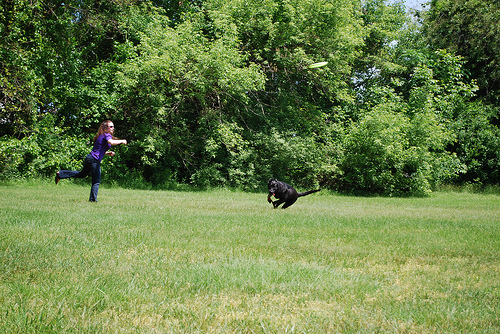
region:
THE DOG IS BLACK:
[260, 166, 328, 220]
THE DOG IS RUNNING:
[257, 172, 328, 220]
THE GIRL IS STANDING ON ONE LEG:
[46, 114, 135, 203]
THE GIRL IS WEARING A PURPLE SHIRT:
[83, 130, 116, 162]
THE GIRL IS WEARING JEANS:
[52, 153, 104, 199]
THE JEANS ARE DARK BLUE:
[56, 149, 102, 200]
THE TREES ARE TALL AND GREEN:
[1, 0, 499, 214]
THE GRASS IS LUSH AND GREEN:
[1, 178, 496, 332]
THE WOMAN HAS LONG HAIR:
[89, 118, 114, 138]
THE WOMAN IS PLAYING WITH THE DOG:
[48, 107, 325, 225]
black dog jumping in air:
[257, 173, 327, 217]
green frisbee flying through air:
[302, 55, 332, 76]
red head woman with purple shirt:
[51, 114, 138, 208]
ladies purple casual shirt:
[82, 128, 124, 164]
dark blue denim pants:
[42, 147, 112, 209]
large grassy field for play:
[14, 170, 492, 325]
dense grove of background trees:
[6, 4, 496, 205]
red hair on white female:
[91, 118, 116, 145]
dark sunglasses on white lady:
[104, 118, 115, 133]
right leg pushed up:
[52, 146, 111, 208]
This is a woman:
[45, 114, 139, 210]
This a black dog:
[258, 168, 326, 213]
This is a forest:
[8, 0, 498, 182]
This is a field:
[10, 169, 487, 328]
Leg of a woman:
[86, 159, 106, 204]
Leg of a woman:
[46, 155, 90, 183]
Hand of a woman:
[105, 134, 133, 146]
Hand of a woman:
[100, 147, 121, 163]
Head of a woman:
[100, 114, 123, 133]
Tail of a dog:
[293, 180, 325, 200]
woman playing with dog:
[1, 1, 499, 330]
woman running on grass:
[50, 116, 130, 204]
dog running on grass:
[264, 175, 323, 211]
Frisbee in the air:
[307, 58, 329, 70]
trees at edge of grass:
[0, 0, 496, 198]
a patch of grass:
[0, 210, 495, 330]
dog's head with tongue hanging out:
[261, 175, 278, 196]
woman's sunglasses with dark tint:
[105, 116, 117, 126]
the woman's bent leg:
[51, 161, 87, 182]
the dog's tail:
[297, 185, 322, 198]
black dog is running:
[266, 176, 322, 208]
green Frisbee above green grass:
[309, 57, 329, 70]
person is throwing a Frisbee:
[51, 117, 136, 205]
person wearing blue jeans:
[58, 157, 103, 197]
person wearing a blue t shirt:
[90, 128, 110, 164]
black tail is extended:
[296, 184, 323, 201]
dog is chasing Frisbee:
[263, 176, 323, 210]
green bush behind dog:
[328, 100, 433, 200]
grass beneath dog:
[9, 177, 498, 332]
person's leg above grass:
[55, 163, 92, 185]